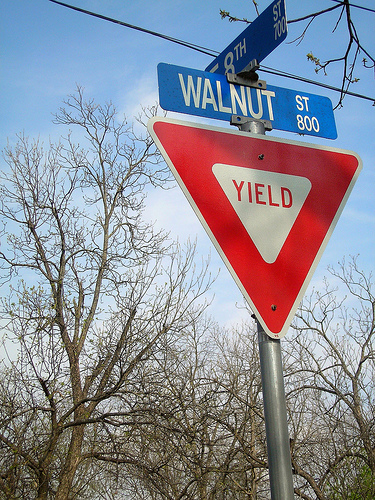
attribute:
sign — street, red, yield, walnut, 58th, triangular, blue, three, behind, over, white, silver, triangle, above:
[80, 48, 366, 363]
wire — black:
[63, 8, 223, 56]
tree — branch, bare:
[14, 188, 174, 408]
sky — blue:
[81, 53, 161, 93]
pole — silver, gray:
[243, 337, 283, 454]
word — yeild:
[224, 165, 327, 212]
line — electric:
[97, 2, 173, 38]